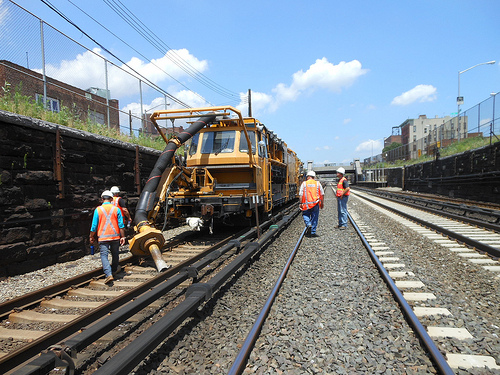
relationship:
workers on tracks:
[83, 189, 129, 292] [1, 184, 303, 374]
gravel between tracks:
[137, 181, 499, 371] [1, 184, 303, 374]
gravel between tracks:
[137, 181, 499, 371] [351, 180, 499, 275]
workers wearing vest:
[331, 166, 355, 233] [334, 176, 353, 200]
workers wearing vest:
[298, 168, 326, 240] [300, 179, 324, 211]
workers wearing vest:
[105, 185, 136, 248] [111, 195, 128, 224]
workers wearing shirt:
[83, 189, 129, 292] [89, 204, 124, 242]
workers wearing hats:
[331, 166, 355, 233] [334, 163, 347, 177]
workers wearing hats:
[298, 168, 326, 240] [304, 169, 317, 179]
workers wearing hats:
[105, 185, 136, 248] [109, 184, 120, 194]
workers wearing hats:
[83, 189, 129, 292] [99, 189, 115, 203]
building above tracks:
[1, 58, 127, 136] [1, 184, 303, 374]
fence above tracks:
[1, 0, 207, 147] [1, 184, 303, 374]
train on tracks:
[160, 124, 312, 234] [1, 184, 303, 374]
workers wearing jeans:
[331, 166, 355, 233] [335, 192, 350, 227]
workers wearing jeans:
[298, 168, 326, 240] [301, 202, 324, 234]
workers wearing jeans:
[83, 189, 129, 292] [95, 236, 122, 273]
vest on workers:
[334, 176, 353, 200] [331, 166, 355, 233]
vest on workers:
[300, 179, 324, 211] [298, 168, 326, 240]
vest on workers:
[111, 195, 128, 224] [105, 185, 136, 248]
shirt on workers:
[89, 204, 124, 242] [83, 189, 129, 292]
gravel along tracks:
[137, 181, 499, 371] [1, 184, 303, 374]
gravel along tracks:
[137, 181, 499, 371] [351, 180, 499, 275]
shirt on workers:
[86, 204, 127, 234] [83, 189, 129, 292]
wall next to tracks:
[1, 110, 196, 283] [1, 184, 303, 374]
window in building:
[34, 88, 62, 116] [1, 58, 127, 136]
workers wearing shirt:
[83, 189, 129, 292] [86, 204, 127, 234]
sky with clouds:
[1, 1, 498, 170] [388, 82, 438, 115]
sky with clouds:
[1, 1, 498, 170] [235, 49, 371, 136]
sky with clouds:
[1, 1, 498, 170] [29, 44, 211, 92]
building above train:
[1, 58, 127, 136] [160, 124, 312, 234]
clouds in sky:
[388, 82, 438, 115] [1, 1, 498, 170]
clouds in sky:
[235, 49, 371, 136] [1, 1, 498, 170]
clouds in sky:
[29, 44, 211, 92] [1, 1, 498, 170]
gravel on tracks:
[137, 181, 499, 371] [1, 184, 303, 374]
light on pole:
[484, 59, 495, 69] [456, 54, 497, 136]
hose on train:
[129, 109, 219, 277] [160, 124, 312, 234]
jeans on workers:
[335, 192, 350, 227] [83, 189, 129, 292]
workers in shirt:
[83, 189, 129, 292] [86, 204, 127, 234]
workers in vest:
[298, 168, 326, 240] [300, 179, 324, 211]